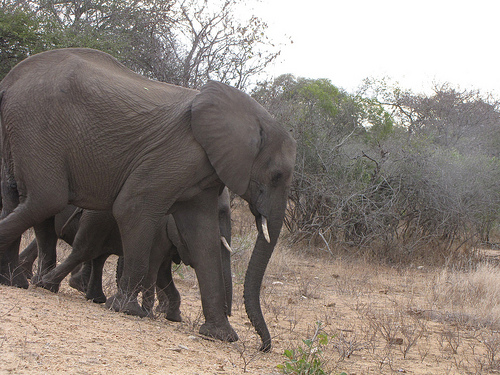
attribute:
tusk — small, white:
[205, 199, 294, 271]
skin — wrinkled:
[45, 115, 183, 214]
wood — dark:
[302, 139, 487, 289]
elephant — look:
[43, 52, 304, 257]